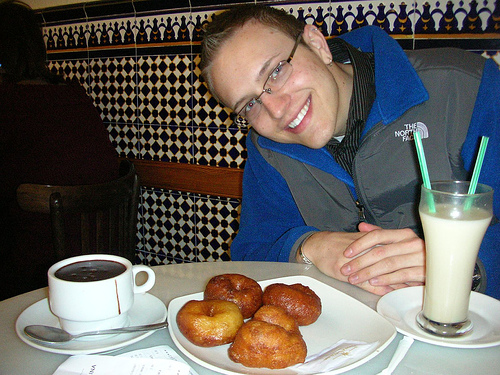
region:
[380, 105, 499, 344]
glass of milk on table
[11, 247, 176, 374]
white cup and saucer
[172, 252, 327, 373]
doughnuts on plate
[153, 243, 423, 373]
white square plate on table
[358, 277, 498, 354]
round white saucer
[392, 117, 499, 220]
two green straws in milk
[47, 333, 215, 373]
receipt slips on table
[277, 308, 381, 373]
sugar packet on plate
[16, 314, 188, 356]
silver teaspoon on plate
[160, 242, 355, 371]
donuts on the plate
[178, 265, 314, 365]
donuts on the plate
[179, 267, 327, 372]
donuts on the plate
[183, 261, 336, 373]
donuts on the plate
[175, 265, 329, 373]
donuts on the plate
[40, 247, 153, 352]
a cup of chocolate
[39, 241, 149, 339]
a cup of chocolate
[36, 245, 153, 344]
a cup of chocolate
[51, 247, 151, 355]
a cup of chocolate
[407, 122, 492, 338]
Two green straws in a glass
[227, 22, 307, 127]
A pair of eyeglasses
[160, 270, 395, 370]
Four donuts on a white plate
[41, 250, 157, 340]
A white coffee mug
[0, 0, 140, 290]
Person sitting in a brown chair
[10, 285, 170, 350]
A spoon on a small plate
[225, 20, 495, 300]
A blue and gray jacket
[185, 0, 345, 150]
The guy is smiling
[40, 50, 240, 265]
Black and white tiles on the wall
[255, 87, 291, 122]
Nose on the guy's face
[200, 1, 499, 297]
Man sitting by the table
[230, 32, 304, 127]
Glasses on the man's face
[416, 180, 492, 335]
Glass on the table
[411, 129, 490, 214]
Straws in the glass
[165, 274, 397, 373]
Plate on the table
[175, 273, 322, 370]
Doughnuts on the plate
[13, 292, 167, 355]
Saucer on the table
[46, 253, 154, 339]
Mug on the saucer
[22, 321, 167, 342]
Spoon on the saucer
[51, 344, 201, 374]
Receipt on the table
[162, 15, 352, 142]
a man smiling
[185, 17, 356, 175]
a man wearing glasses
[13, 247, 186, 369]
a white saucer with a spoon on it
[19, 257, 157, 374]
a coffee mug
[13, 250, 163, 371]
a coffee mug on a saucer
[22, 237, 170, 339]
a white coffee mug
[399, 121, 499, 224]
two green straws in a glass